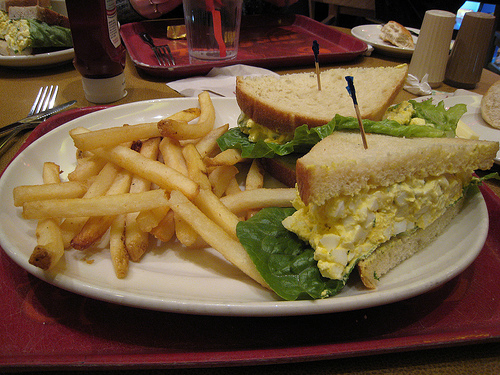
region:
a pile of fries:
[13, 92, 298, 300]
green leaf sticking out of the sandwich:
[236, 205, 366, 309]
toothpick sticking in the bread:
[343, 72, 378, 149]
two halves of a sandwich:
[228, 47, 497, 306]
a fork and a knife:
[5, 76, 84, 171]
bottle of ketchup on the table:
[60, 3, 140, 100]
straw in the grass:
[206, 7, 231, 61]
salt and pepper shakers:
[407, 3, 496, 90]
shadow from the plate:
[31, 280, 478, 372]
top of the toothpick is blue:
[343, 72, 363, 104]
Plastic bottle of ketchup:
[66, 3, 128, 104]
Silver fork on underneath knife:
[0, 83, 60, 164]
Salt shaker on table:
[408, 8, 455, 90]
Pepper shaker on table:
[445, 10, 494, 88]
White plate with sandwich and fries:
[1, 63, 498, 315]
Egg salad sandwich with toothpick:
[210, 36, 469, 188]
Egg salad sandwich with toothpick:
[235, 74, 498, 301]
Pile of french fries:
[12, 91, 298, 295]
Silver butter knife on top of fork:
[0, 98, 76, 137]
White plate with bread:
[350, 19, 425, 56]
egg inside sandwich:
[290, 171, 475, 261]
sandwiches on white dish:
[0, 56, 499, 321]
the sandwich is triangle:
[290, 111, 497, 291]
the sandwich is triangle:
[225, 55, 415, 141]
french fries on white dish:
[10, 93, 270, 291]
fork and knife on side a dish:
[0, 75, 93, 170]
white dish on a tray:
[0, 62, 496, 368]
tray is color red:
[0, 95, 499, 373]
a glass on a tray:
[172, 0, 243, 66]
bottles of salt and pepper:
[406, 5, 493, 100]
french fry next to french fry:
[12, 181, 96, 203]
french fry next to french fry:
[70, 128, 201, 198]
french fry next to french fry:
[73, 121, 166, 152]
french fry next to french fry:
[156, 92, 217, 139]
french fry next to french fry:
[165, 188, 275, 291]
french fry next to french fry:
[218, 187, 298, 213]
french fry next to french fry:
[110, 218, 129, 275]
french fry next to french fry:
[125, 135, 159, 260]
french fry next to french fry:
[66, 166, 130, 250]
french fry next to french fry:
[197, 124, 230, 162]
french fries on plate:
[15, 98, 275, 276]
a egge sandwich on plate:
[282, 115, 488, 300]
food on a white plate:
[1, 43, 496, 338]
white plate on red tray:
[0, 68, 499, 373]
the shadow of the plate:
[11, 288, 497, 372]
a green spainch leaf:
[218, 180, 347, 298]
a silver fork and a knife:
[1, 75, 73, 159]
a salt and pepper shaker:
[381, 1, 499, 94]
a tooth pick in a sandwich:
[333, 60, 400, 161]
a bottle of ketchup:
[53, 0, 148, 107]